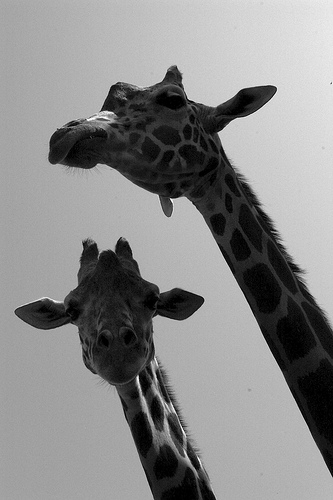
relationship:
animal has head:
[41, 63, 333, 479] [39, 55, 280, 202]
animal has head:
[41, 63, 333, 479] [44, 62, 277, 196]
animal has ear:
[41, 63, 333, 479] [155, 286, 203, 321]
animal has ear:
[41, 63, 333, 479] [13, 297, 70, 329]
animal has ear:
[13, 236, 217, 499] [209, 84, 277, 132]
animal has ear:
[13, 236, 217, 499] [11, 294, 71, 330]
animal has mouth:
[13, 236, 217, 499] [93, 348, 150, 388]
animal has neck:
[41, 63, 333, 479] [125, 379, 218, 495]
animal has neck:
[41, 63, 333, 479] [199, 168, 332, 478]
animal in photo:
[41, 63, 333, 479] [1, 1, 330, 493]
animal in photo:
[13, 236, 217, 499] [1, 1, 330, 493]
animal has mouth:
[41, 116, 110, 170] [39, 130, 106, 173]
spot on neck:
[274, 295, 315, 362] [219, 181, 331, 385]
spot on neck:
[243, 262, 282, 312] [219, 181, 331, 385]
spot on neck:
[227, 227, 252, 261] [219, 181, 331, 385]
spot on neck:
[265, 237, 299, 294] [219, 181, 331, 385]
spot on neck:
[239, 202, 264, 252] [219, 181, 331, 385]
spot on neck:
[150, 394, 164, 431] [109, 361, 220, 499]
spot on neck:
[166, 412, 184, 455] [109, 361, 220, 499]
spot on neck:
[151, 443, 177, 480] [109, 361, 220, 499]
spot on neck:
[131, 411, 152, 458] [109, 361, 220, 499]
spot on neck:
[186, 441, 200, 472] [109, 361, 220, 499]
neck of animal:
[219, 181, 331, 385] [41, 63, 333, 479]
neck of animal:
[109, 361, 220, 499] [13, 236, 217, 499]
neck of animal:
[193, 164, 332, 476] [41, 63, 333, 479]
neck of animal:
[97, 362, 228, 490] [13, 236, 217, 499]